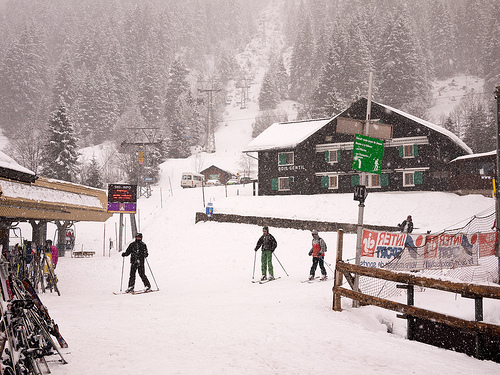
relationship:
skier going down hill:
[113, 220, 156, 306] [57, 275, 179, 361]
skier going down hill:
[302, 219, 332, 338] [153, 283, 339, 345]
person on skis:
[118, 232, 156, 292] [112, 286, 162, 296]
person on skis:
[252, 221, 282, 277] [247, 278, 287, 285]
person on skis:
[304, 227, 326, 278] [300, 278, 332, 288]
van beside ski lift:
[177, 169, 205, 188] [112, 129, 159, 208]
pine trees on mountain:
[2, 9, 144, 151] [2, 2, 482, 186]